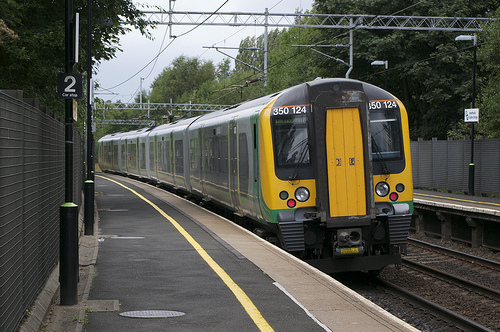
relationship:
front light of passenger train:
[282, 197, 295, 206] [97, 77, 414, 273]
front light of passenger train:
[293, 185, 310, 203] [97, 77, 414, 273]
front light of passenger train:
[391, 177, 408, 194] [97, 77, 414, 273]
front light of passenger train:
[375, 181, 390, 197] [97, 77, 414, 273]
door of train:
[325, 112, 366, 214] [239, 67, 415, 246]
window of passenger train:
[274, 115, 311, 167] [97, 77, 414, 273]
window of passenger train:
[370, 121, 401, 152] [97, 77, 414, 273]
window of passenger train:
[202, 140, 230, 172] [97, 77, 414, 273]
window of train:
[205, 135, 229, 174] [98, 80, 413, 260]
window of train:
[179, 133, 188, 178] [139, 75, 417, 256]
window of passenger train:
[154, 137, 171, 179] [97, 77, 414, 273]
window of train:
[112, 135, 132, 159] [289, 91, 344, 274]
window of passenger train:
[99, 141, 118, 163] [97, 77, 414, 273]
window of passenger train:
[205, 135, 229, 174] [97, 77, 414, 273]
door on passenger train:
[325, 108, 367, 217] [97, 77, 414, 273]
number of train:
[273, 107, 280, 114] [277, 100, 367, 235]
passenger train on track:
[97, 77, 414, 273] [328, 266, 499, 330]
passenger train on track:
[97, 77, 414, 273] [378, 237, 499, 332]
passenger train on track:
[101, 75, 426, 273] [373, 232, 498, 327]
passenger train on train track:
[97, 77, 414, 273] [381, 280, 439, 317]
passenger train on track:
[97, 77, 414, 273] [364, 247, 491, 311]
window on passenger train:
[276, 126, 310, 166] [97, 77, 414, 273]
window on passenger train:
[370, 121, 398, 152] [97, 77, 414, 273]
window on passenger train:
[239, 137, 249, 178] [97, 77, 414, 273]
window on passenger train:
[205, 135, 229, 174] [97, 77, 414, 273]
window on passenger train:
[190, 140, 197, 169] [97, 77, 414, 273]